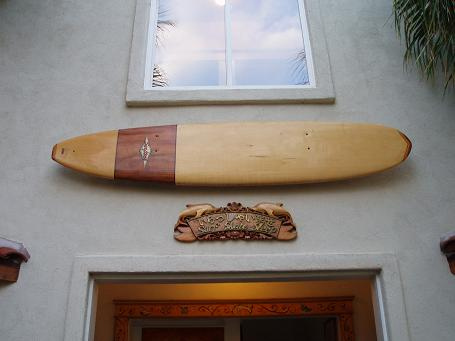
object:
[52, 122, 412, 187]
board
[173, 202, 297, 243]
sign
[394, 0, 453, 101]
tree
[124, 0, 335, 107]
window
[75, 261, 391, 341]
doorway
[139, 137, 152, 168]
decal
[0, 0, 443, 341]
wall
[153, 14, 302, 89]
reflection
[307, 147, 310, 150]
hole